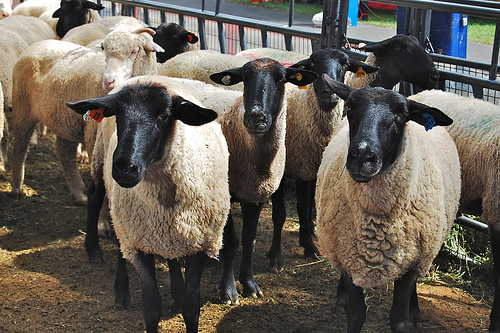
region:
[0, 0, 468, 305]
several sheep standing in a pen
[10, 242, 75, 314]
brown dirt floor of the pen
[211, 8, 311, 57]
black metal fence of the pen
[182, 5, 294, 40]
black metal rail of the fence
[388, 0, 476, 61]
a blue bin outside of the pen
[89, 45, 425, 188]
the black heads of several sheep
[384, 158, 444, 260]
tan fleece of the sheep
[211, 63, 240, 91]
white tag in the ear of the sheep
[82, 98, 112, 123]
red tag in the ear of the sheep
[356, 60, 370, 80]
yellow tag in the ear of the sheep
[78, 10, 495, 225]
A flock of sheep have tags in their ears.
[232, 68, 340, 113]
A sheep has a yellow tag in its ear.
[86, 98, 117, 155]
A sheep has a red tag in its ear.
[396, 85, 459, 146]
A sheep has a blue tag in its ear.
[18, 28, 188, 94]
A white sheep has a white snout.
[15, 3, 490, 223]
A flock of sheep are behind a fence.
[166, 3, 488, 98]
a fence surrounds a flock of sheep.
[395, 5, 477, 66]
A blue post is next to a fence.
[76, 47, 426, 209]
4 sheep are reacting attentive.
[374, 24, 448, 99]
A sheep is standing close to a fence.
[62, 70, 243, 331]
sheep in a pen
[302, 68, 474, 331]
sheep in a pen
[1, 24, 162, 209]
sheep in a pen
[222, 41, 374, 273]
sheep in a pen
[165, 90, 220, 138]
ear of a sheep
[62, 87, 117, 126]
ear of a sheep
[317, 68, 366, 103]
ear of a sheep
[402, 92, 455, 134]
ear of a sheep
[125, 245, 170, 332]
black leg of a sheep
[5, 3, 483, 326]
a herd of sheep are in an enclosure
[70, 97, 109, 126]
a white and red tag is on the sheep's ear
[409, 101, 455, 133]
the sheep's ear has a blue tag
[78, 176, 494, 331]
the sheep have black legs and hooves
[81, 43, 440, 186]
the heads of the sheep are black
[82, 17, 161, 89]
a white sheep has horns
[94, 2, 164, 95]
the sheep has a white head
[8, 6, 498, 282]
the herd of sheep has white wool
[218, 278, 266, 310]
the hooves are forked on the sheep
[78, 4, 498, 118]
a fence is behind the sheep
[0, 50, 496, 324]
small herd of sheep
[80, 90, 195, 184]
sheep with black fur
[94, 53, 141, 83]
sheep with white fur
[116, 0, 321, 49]
gate to keep sheep together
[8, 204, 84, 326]
shadow of sheep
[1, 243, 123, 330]
ground for sheep to walk on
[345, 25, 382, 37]
paved road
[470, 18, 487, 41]
short green grass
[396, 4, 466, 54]
blue bin of some sort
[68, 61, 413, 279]
sheep looking in same direction